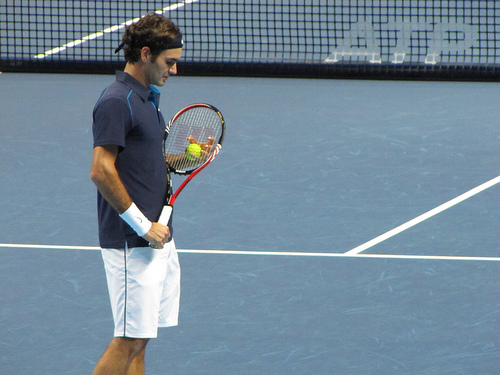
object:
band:
[119, 202, 154, 238]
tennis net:
[1, 0, 500, 85]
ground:
[431, 140, 473, 160]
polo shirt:
[90, 69, 174, 248]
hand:
[184, 135, 216, 165]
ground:
[256, 83, 343, 120]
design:
[179, 37, 186, 46]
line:
[0, 241, 500, 262]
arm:
[89, 97, 136, 226]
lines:
[341, 159, 499, 255]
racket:
[146, 102, 225, 250]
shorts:
[100, 235, 182, 341]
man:
[90, 10, 216, 375]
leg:
[92, 247, 166, 374]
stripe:
[120, 242, 128, 337]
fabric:
[115, 34, 183, 54]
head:
[121, 13, 184, 86]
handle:
[148, 204, 173, 250]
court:
[1, 0, 500, 375]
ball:
[183, 143, 201, 161]